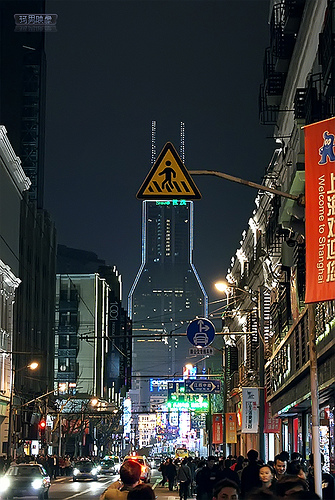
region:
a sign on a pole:
[141, 150, 232, 222]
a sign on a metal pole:
[113, 141, 265, 277]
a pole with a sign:
[120, 144, 309, 242]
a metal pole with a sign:
[129, 156, 286, 243]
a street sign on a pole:
[130, 124, 273, 246]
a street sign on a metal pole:
[125, 132, 240, 253]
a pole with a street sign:
[132, 127, 240, 257]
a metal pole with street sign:
[121, 134, 219, 225]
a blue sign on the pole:
[171, 300, 277, 413]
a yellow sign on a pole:
[143, 151, 280, 248]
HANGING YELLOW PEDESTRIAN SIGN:
[136, 137, 205, 199]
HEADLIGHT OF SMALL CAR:
[26, 478, 46, 491]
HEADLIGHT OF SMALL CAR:
[0, 475, 12, 491]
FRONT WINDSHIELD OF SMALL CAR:
[2, 462, 43, 475]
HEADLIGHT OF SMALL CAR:
[71, 465, 81, 475]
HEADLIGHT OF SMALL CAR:
[88, 465, 99, 476]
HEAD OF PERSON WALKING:
[257, 462, 274, 484]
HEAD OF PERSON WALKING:
[271, 454, 288, 477]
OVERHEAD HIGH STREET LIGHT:
[25, 358, 43, 373]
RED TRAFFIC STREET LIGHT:
[35, 415, 48, 434]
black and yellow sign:
[137, 143, 191, 212]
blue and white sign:
[178, 293, 222, 356]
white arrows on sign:
[179, 312, 218, 344]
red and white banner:
[297, 127, 333, 291]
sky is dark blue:
[68, 56, 139, 150]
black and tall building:
[6, 40, 50, 436]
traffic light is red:
[30, 412, 53, 434]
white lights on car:
[2, 463, 50, 495]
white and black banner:
[238, 383, 262, 432]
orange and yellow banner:
[227, 401, 241, 446]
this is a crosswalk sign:
[119, 135, 217, 212]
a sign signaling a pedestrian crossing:
[133, 128, 203, 208]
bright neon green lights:
[157, 388, 224, 423]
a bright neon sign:
[161, 397, 219, 416]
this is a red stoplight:
[37, 419, 47, 429]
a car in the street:
[4, 455, 60, 498]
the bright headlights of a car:
[72, 467, 99, 482]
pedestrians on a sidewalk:
[167, 431, 333, 497]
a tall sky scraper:
[122, 113, 224, 475]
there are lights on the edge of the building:
[128, 100, 222, 486]